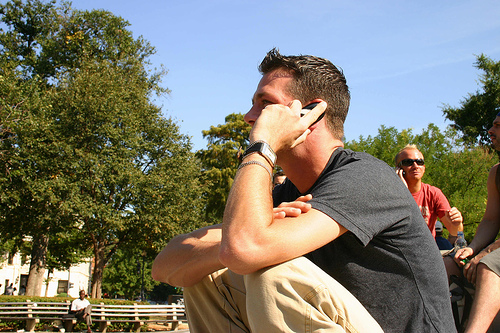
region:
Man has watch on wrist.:
[235, 137, 282, 193]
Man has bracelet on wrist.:
[221, 156, 288, 197]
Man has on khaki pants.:
[231, 282, 306, 319]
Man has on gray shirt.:
[324, 175, 391, 298]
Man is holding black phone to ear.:
[268, 82, 328, 214]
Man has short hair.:
[246, 43, 368, 185]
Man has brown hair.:
[263, 37, 348, 166]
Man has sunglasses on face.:
[397, 155, 427, 192]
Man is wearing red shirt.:
[408, 181, 454, 260]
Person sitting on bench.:
[49, 280, 81, 310]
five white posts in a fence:
[1, 292, 186, 330]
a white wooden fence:
[2, 294, 187, 329]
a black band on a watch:
[235, 131, 283, 181]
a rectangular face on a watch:
[234, 127, 292, 194]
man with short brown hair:
[132, 44, 479, 329]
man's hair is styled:
[142, 32, 462, 322]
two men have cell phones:
[138, 18, 498, 329]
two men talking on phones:
[97, 20, 471, 324]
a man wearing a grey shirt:
[152, 21, 462, 323]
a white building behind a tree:
[0, 198, 105, 316]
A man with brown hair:
[227, 25, 371, 203]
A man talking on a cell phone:
[217, 41, 448, 277]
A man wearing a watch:
[208, 32, 413, 254]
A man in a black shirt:
[197, 32, 494, 332]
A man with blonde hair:
[388, 135, 474, 267]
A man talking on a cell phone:
[394, 135, 470, 275]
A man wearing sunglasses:
[374, 130, 477, 258]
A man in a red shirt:
[375, 135, 471, 267]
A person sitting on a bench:
[63, 279, 108, 329]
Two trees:
[0, 1, 145, 306]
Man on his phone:
[329, 87, 463, 229]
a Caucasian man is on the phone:
[172, 45, 364, 329]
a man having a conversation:
[139, 40, 419, 315]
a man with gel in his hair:
[192, 17, 484, 284]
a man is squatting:
[78, 37, 463, 329]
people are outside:
[30, 35, 464, 253]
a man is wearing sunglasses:
[372, 110, 496, 275]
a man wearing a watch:
[110, 47, 424, 332]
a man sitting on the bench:
[28, 175, 138, 332]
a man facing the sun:
[350, 116, 487, 288]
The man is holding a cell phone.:
[267, 65, 329, 149]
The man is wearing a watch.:
[232, 111, 294, 176]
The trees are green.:
[35, 45, 122, 180]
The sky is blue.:
[153, 37, 233, 104]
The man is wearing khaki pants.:
[172, 212, 339, 326]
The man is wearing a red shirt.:
[382, 155, 462, 238]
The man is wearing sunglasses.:
[395, 151, 431, 170]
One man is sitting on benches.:
[57, 272, 97, 326]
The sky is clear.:
[40, 5, 485, 139]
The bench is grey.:
[104, 294, 176, 323]